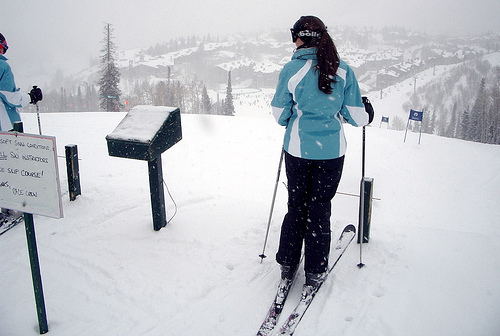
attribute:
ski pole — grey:
[356, 96, 368, 270]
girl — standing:
[271, 16, 373, 286]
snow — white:
[1, 111, 500, 335]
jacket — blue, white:
[272, 48, 369, 160]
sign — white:
[0, 133, 64, 335]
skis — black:
[257, 223, 356, 335]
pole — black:
[25, 214, 49, 336]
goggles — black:
[291, 29, 325, 43]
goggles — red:
[0, 40, 10, 53]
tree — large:
[98, 24, 125, 112]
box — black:
[106, 105, 181, 231]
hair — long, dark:
[294, 15, 339, 93]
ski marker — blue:
[404, 108, 426, 144]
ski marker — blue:
[381, 116, 392, 127]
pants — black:
[276, 151, 345, 273]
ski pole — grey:
[260, 124, 288, 266]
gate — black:
[283, 176, 376, 244]